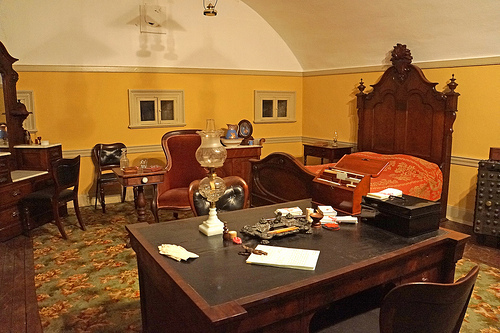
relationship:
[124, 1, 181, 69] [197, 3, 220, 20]
shadow of ceiling lantern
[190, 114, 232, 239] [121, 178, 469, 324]
lamp on table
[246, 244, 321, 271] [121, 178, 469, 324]
papers on table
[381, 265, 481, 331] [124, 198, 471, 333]
chair at desk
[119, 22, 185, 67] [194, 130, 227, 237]
shadow of lamp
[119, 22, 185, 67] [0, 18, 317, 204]
shadow on wall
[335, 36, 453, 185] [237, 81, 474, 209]
headboard on bed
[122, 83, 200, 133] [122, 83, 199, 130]
white frame on window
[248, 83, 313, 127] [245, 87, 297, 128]
white frame on window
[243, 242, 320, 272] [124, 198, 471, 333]
papers on desk